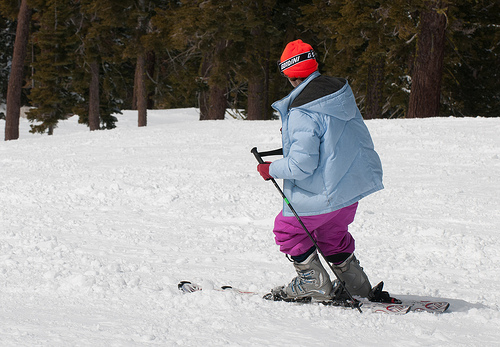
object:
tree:
[23, 0, 76, 135]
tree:
[70, 0, 136, 131]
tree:
[168, 0, 276, 121]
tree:
[322, 0, 500, 117]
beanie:
[277, 39, 318, 78]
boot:
[271, 245, 346, 302]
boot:
[330, 254, 384, 301]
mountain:
[0, 108, 500, 347]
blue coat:
[271, 70, 384, 217]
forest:
[3, 0, 500, 139]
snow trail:
[7, 140, 480, 343]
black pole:
[250, 146, 363, 314]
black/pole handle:
[251, 147, 265, 164]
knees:
[273, 202, 359, 256]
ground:
[0, 107, 500, 347]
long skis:
[177, 281, 449, 315]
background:
[2, 1, 498, 141]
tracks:
[16, 174, 239, 304]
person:
[250, 39, 383, 300]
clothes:
[256, 38, 372, 305]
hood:
[289, 75, 356, 122]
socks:
[291, 245, 317, 262]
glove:
[257, 161, 272, 181]